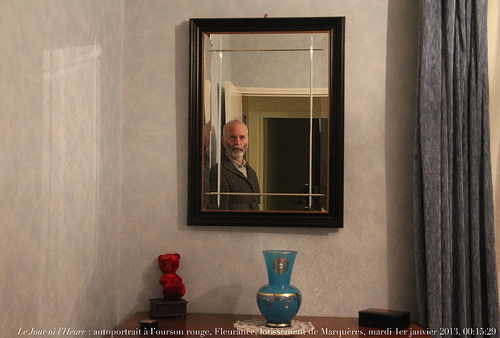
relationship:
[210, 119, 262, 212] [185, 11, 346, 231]
man in mirror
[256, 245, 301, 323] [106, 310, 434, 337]
vase on chest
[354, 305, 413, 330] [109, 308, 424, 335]
box on desk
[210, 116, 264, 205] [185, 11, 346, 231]
man reflecting in mirror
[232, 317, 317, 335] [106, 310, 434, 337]
doilie on chest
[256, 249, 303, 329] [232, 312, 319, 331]
vase on doily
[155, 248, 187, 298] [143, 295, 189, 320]
bear on box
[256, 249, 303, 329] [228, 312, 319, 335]
vase on doily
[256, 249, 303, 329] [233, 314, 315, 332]
vase on doily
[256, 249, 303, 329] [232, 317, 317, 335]
vase on doilie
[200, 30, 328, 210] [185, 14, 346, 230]
mirror with frame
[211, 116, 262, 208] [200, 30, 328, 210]
reflection in mirror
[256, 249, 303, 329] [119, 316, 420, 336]
vase on table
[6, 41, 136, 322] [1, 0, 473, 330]
wall in room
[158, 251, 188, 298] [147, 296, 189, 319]
bear on box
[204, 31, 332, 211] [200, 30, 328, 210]
reflection in mirror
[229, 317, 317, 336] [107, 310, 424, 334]
doilie on chest